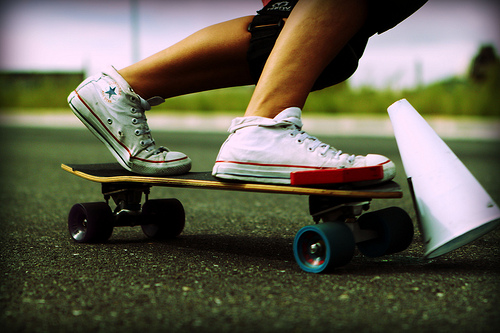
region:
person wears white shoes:
[81, 55, 241, 203]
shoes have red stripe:
[50, 85, 160, 185]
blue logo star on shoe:
[86, 70, 141, 115]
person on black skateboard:
[101, 120, 351, 226]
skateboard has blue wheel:
[270, 205, 325, 277]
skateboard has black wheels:
[40, 191, 170, 251]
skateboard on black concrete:
[25, 235, 255, 315]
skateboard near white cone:
[356, 102, 491, 237]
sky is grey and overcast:
[30, 25, 103, 62]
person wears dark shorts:
[220, 4, 320, 61]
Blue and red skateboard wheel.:
[289, 205, 362, 279]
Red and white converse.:
[57, 57, 191, 186]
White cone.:
[368, 79, 498, 291]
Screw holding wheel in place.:
[306, 240, 318, 255]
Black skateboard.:
[51, 151, 407, 203]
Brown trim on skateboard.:
[54, 153, 408, 203]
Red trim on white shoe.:
[212, 155, 401, 170]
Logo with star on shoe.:
[92, 76, 123, 108]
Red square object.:
[281, 163, 392, 190]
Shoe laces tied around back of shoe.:
[226, 108, 310, 134]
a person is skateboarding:
[30, 7, 408, 281]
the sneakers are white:
[42, 32, 392, 187]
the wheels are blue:
[264, 202, 413, 278]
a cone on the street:
[367, 76, 489, 281]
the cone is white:
[375, 71, 495, 276]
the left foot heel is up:
[65, 57, 185, 172]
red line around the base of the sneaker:
[65, 90, 183, 167]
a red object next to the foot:
[282, 151, 379, 195]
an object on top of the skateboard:
[278, 135, 393, 199]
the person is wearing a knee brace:
[233, 1, 369, 88]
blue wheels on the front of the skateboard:
[294, 207, 411, 274]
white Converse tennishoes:
[65, 67, 392, 181]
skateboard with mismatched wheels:
[55, 162, 412, 269]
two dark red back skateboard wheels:
[72, 202, 184, 242]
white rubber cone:
[388, 96, 498, 259]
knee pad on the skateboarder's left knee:
[255, 7, 358, 87]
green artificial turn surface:
[5, 125, 494, 329]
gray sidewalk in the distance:
[6, 110, 498, 132]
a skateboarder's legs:
[67, 2, 414, 177]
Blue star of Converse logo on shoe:
[102, 83, 120, 104]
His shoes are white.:
[215, 118, 396, 185]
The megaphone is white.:
[381, 95, 488, 264]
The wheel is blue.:
[287, 215, 354, 275]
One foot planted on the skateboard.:
[210, 113, 392, 187]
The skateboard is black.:
[50, 153, 413, 285]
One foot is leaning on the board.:
[65, 60, 192, 175]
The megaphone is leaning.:
[382, 91, 490, 262]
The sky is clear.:
[15, 16, 125, 63]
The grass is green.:
[415, 82, 498, 112]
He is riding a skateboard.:
[8, 121, 492, 331]